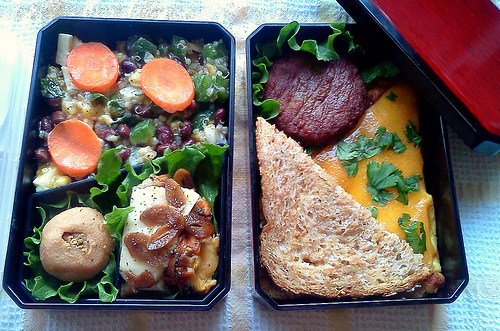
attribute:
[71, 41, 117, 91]
carrot — round, orange, sliced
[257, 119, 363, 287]
bread — wheat, sliced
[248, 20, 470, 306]
container — blue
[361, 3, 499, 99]
top of container — wooden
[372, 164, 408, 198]
parsley — green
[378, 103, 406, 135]
cheese — melted, yellow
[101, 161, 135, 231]
leaf of lettuce — crisp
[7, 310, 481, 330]
tablecloth — white, yellow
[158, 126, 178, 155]
kidney beans — shiny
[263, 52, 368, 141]
meat — hamburger patty, brown, round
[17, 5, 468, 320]
bento box — black